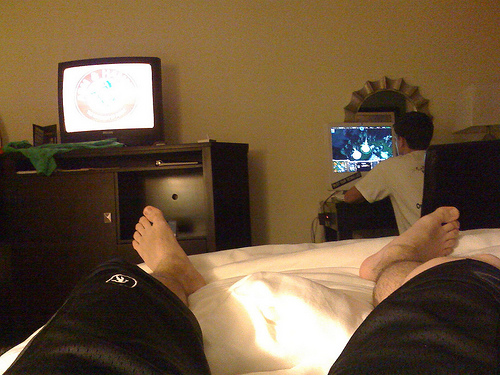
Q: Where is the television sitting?
A: Top of dresser.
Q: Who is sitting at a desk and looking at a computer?
A: Young boy.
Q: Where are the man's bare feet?
A: On bed.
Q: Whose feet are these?
A: The photographer's.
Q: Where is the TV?
A: On the brown dresser.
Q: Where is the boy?
A: In front of the computer.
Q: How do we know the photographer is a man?
A: His legs are very hairy.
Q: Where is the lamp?
A: Next to the computer.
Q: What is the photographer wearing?
A: Black shorts.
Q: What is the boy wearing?
A: A white t-shirt.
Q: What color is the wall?
A: White.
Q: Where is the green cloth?
A: In front of the television.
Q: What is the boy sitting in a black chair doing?
A: Playing a computer game.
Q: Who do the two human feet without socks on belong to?
A: The person in bed.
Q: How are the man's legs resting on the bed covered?
A: With black pants.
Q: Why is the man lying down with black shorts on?
A: He didn't feel like changing into pajamas.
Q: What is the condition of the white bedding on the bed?
A: Wrinkled.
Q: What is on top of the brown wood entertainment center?
A: TV.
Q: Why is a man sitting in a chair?
A: He is using the computer.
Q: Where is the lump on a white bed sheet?
A: Between the man's legs.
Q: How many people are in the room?
A: Two.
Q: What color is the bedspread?
A: White.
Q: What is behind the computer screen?
A: A mirror.